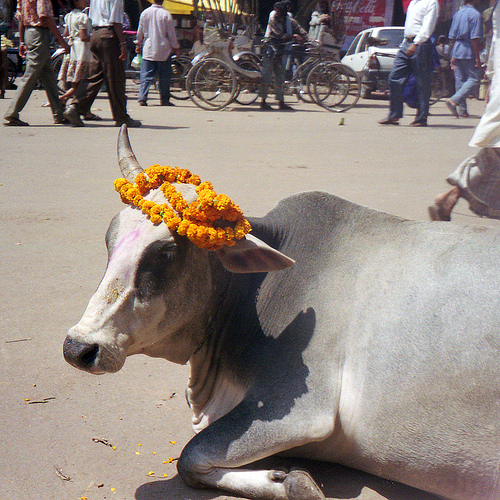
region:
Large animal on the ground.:
[56, 120, 493, 496]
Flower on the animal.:
[103, 163, 255, 248]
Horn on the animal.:
[106, 123, 147, 186]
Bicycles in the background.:
[131, 29, 364, 116]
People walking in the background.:
[8, 1, 498, 218]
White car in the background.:
[341, 24, 441, 107]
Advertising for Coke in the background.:
[324, 3, 408, 48]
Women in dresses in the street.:
[53, 10, 499, 212]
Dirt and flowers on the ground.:
[6, 334, 194, 499]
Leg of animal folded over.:
[179, 383, 354, 498]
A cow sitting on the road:
[66, 111, 499, 475]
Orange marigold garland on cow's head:
[71, 108, 295, 390]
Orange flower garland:
[105, 153, 248, 242]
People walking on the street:
[14, 3, 189, 160]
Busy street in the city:
[1, 0, 498, 185]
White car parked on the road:
[348, 16, 429, 96]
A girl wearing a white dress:
[57, 1, 93, 117]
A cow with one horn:
[63, 115, 278, 409]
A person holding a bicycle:
[227, 0, 368, 123]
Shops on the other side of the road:
[175, 0, 490, 72]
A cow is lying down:
[65, 122, 496, 497]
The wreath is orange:
[113, 166, 249, 250]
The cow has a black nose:
[62, 331, 97, 371]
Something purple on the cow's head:
[112, 224, 139, 256]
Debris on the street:
[23, 391, 175, 496]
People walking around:
[12, 1, 173, 127]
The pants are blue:
[388, 35, 436, 123]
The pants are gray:
[11, 27, 66, 118]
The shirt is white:
[138, 7, 178, 60]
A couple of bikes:
[190, 45, 362, 114]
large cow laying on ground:
[34, 120, 499, 486]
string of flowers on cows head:
[111, 153, 249, 250]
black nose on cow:
[59, 329, 110, 367]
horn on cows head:
[100, 114, 155, 191]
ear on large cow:
[205, 218, 292, 279]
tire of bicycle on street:
[185, 51, 233, 114]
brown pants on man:
[76, 25, 136, 130]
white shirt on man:
[130, 2, 181, 64]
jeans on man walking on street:
[384, 32, 434, 142]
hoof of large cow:
[279, 471, 329, 498]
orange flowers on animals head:
[108, 163, 250, 255]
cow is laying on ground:
[63, 118, 498, 498]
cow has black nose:
[61, 338, 101, 367]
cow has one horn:
[105, 122, 261, 248]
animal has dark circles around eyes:
[102, 215, 187, 300]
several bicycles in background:
[170, 35, 359, 112]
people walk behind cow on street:
[0, 0, 499, 218]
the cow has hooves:
[271, 463, 331, 498]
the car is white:
[340, 25, 407, 93]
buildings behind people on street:
[0, 0, 499, 78]